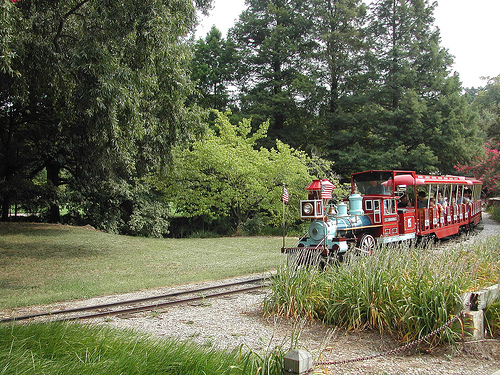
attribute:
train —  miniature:
[275, 167, 485, 267]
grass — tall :
[264, 239, 499, 346]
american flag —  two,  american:
[280, 184, 289, 205]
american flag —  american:
[317, 180, 332, 200]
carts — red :
[393, 164, 493, 252]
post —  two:
[458, 285, 498, 335]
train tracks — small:
[1, 271, 283, 329]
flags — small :
[244, 152, 354, 231]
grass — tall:
[0, 322, 295, 373]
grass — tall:
[260, 231, 498, 353]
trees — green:
[110, 41, 356, 211]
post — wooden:
[282, 345, 315, 371]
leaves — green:
[3, 1, 498, 237]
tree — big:
[2, 2, 220, 234]